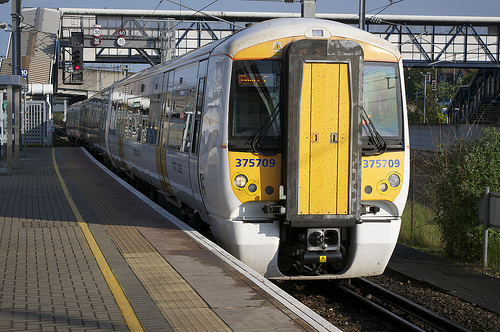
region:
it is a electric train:
[66, 24, 413, 284]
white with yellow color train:
[81, 15, 408, 281]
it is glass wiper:
[246, 88, 283, 153]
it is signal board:
[71, 40, 87, 78]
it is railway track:
[337, 289, 439, 329]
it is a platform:
[0, 150, 185, 329]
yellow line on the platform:
[51, 201, 139, 328]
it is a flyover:
[397, 17, 498, 67]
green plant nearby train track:
[440, 129, 492, 254]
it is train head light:
[233, 171, 259, 196]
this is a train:
[190, 75, 427, 296]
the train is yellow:
[60, 35, 285, 246]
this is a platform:
[100, 199, 220, 303]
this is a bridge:
[82, 22, 155, 36]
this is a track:
[330, 271, 395, 316]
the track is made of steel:
[376, 244, 438, 330]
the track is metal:
[373, 281, 420, 326]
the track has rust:
[276, 298, 380, 316]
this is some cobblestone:
[62, 240, 102, 267]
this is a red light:
[62, 39, 99, 114]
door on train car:
[293, 52, 357, 219]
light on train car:
[233, 173, 248, 188]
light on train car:
[386, 171, 401, 187]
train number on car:
[233, 154, 276, 166]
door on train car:
[193, 73, 204, 203]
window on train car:
[228, 63, 288, 157]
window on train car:
[364, 57, 404, 149]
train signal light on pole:
[71, 45, 84, 77]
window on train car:
[167, 82, 195, 150]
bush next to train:
[425, 108, 497, 254]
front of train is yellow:
[207, 23, 403, 245]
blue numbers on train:
[205, 128, 418, 186]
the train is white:
[47, 16, 425, 285]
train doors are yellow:
[110, 65, 187, 201]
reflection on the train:
[66, 83, 238, 209]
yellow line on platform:
[32, 131, 172, 328]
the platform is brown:
[0, 130, 312, 330]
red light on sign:
[70, 58, 83, 75]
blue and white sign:
[16, 60, 31, 79]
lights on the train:
[234, 65, 274, 90]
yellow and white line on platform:
[3, 144, 330, 329]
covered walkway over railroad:
[68, 12, 496, 61]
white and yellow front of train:
[228, 21, 406, 276]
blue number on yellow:
[234, 156, 276, 171]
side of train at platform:
[74, 68, 218, 159]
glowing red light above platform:
[72, 43, 84, 73]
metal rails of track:
[335, 278, 461, 330]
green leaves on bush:
[433, 136, 498, 261]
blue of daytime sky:
[0, 0, 497, 50]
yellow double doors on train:
[153, 70, 173, 194]